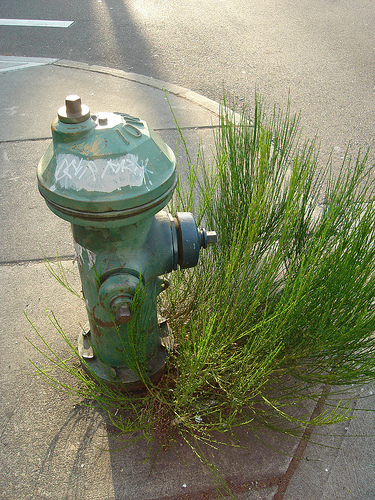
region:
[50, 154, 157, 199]
white graffiti on green firehydrant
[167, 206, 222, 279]
large steel screw on firehydrant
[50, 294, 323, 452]
fire hydrant surrounded by grass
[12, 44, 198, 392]
fire hydrant on sidewalk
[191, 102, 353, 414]
tall green grass growing on sidewalk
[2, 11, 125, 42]
white light painted on street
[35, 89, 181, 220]
fire hydrant green top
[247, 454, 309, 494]
sidewalk brick gray grout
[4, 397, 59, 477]
gray side walk brick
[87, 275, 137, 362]
rust on fire hydrant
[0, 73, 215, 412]
fire hydrant has rust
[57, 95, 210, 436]
fire hydrant is green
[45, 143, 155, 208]
a white graffiti text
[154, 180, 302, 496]
grasses beside the fire hydrant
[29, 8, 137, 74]
a white painted line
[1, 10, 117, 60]
a line on the ground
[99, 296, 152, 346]
the screw is rusty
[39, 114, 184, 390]
the fire hydrant is green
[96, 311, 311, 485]
grasses beside the hydrant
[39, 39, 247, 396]
fire hydrant beside the street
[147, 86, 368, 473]
Tall green grass on sidewalk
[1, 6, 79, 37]
White line on street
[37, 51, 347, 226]
Curb on the sidewalk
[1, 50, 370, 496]
Gray cement sidewalk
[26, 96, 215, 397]
Greenish blue fire hydrant on sidewalk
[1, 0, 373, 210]
Gray asphalt street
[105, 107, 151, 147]
Writing on top of fire hydrant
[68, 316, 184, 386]
Bolts on base of fire hydrant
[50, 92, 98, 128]
Bronze bolt on top of fire hydrant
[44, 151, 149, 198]
White graffiti on fire hydrant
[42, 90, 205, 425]
green metal fire hydrant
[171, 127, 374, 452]
tall green plant growing in sidewalk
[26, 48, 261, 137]
grey concrete sidewalk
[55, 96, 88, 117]
grey metal bolt on fire hydrant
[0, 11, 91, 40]
white stripe painted on concrete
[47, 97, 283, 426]
green fire hydrant next to green plant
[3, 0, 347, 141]
sidewalk next to road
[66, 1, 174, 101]
shadow on concrete road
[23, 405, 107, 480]
shadow of plant on sidewalk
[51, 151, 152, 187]
white graffiti on fire hydrant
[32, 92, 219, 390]
a tall bright green fire hydrant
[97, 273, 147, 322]
the green side of fire hydrant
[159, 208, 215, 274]
the green side of fire hydrant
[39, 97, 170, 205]
the green top of fire hydrant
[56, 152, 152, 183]
white letters written on a hydrant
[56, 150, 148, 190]
paint chipped off a hydrant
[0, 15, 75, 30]
a white line on a raod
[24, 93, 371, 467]
a clump of long green grass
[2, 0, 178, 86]
a shadow on the street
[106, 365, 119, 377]
a bolt on the hydrant